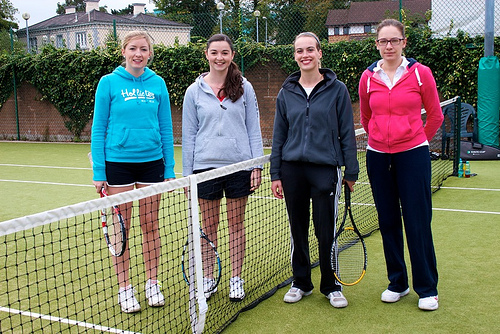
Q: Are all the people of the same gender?
A: Yes, all the people are female.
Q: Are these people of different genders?
A: No, all the people are female.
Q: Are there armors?
A: No, there are no armors.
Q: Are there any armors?
A: No, there are no armors.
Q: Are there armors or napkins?
A: No, there are no armors or napkins.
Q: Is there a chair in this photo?
A: Yes, there is a chair.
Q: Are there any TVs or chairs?
A: Yes, there is a chair.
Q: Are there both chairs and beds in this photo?
A: No, there is a chair but no beds.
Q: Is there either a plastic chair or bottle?
A: Yes, there is a plastic chair.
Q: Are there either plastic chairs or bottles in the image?
A: Yes, there is a plastic chair.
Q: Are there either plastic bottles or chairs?
A: Yes, there is a plastic chair.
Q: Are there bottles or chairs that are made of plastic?
A: Yes, the chair is made of plastic.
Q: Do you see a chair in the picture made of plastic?
A: Yes, there is a chair that is made of plastic.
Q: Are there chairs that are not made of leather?
A: Yes, there is a chair that is made of plastic.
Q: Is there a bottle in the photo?
A: No, there are no bottles.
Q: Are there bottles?
A: No, there are no bottles.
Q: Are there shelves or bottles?
A: No, there are no bottles or shelves.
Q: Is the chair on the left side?
A: No, the chair is on the right of the image.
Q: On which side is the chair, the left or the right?
A: The chair is on the right of the image.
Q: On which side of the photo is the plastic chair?
A: The chair is on the right of the image.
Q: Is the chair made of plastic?
A: Yes, the chair is made of plastic.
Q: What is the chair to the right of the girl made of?
A: The chair is made of plastic.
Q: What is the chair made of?
A: The chair is made of plastic.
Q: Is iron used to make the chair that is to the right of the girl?
A: No, the chair is made of plastic.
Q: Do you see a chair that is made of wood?
A: No, there is a chair but it is made of plastic.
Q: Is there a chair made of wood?
A: No, there is a chair but it is made of plastic.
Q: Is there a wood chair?
A: No, there is a chair but it is made of plastic.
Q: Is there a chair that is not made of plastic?
A: No, there is a chair but it is made of plastic.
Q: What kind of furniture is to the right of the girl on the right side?
A: The piece of furniture is a chair.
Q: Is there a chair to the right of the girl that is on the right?
A: Yes, there is a chair to the right of the girl.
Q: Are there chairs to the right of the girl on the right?
A: Yes, there is a chair to the right of the girl.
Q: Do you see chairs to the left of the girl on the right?
A: No, the chair is to the right of the girl.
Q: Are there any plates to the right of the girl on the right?
A: No, there is a chair to the right of the girl.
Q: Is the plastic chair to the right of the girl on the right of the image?
A: Yes, the chair is to the right of the girl.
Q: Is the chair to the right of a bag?
A: No, the chair is to the right of the girl.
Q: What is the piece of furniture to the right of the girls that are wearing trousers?
A: The piece of furniture is a chair.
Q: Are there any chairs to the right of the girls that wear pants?
A: Yes, there is a chair to the right of the girls.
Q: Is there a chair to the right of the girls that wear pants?
A: Yes, there is a chair to the right of the girls.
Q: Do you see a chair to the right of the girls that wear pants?
A: Yes, there is a chair to the right of the girls.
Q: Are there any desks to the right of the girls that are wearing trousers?
A: No, there is a chair to the right of the girls.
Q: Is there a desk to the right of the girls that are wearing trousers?
A: No, there is a chair to the right of the girls.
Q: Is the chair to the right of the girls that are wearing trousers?
A: Yes, the chair is to the right of the girls.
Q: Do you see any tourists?
A: No, there are no tourists.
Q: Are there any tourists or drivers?
A: No, there are no tourists or drivers.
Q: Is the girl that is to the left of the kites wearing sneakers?
A: Yes, the girl is wearing sneakers.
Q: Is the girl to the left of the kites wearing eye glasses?
A: No, the girl is wearing sneakers.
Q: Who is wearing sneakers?
A: The girl is wearing sneakers.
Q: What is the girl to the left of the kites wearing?
A: The girl is wearing sneakers.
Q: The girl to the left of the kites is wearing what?
A: The girl is wearing sneakers.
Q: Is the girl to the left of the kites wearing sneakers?
A: Yes, the girl is wearing sneakers.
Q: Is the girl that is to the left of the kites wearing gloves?
A: No, the girl is wearing sneakers.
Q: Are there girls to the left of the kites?
A: Yes, there is a girl to the left of the kites.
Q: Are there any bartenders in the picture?
A: No, there are no bartenders.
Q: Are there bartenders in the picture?
A: No, there are no bartenders.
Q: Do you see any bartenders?
A: No, there are no bartenders.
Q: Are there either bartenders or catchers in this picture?
A: No, there are no bartenders or catchers.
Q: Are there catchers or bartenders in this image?
A: No, there are no bartenders or catchers.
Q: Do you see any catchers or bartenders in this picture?
A: No, there are no bartenders or catchers.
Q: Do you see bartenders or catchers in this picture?
A: No, there are no bartenders or catchers.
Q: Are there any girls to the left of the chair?
A: Yes, there is a girl to the left of the chair.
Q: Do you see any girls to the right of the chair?
A: No, the girl is to the left of the chair.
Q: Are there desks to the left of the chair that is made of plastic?
A: No, there is a girl to the left of the chair.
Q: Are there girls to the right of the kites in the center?
A: Yes, there is a girl to the right of the kites.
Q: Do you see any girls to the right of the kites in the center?
A: Yes, there is a girl to the right of the kites.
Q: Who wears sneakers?
A: The girl wears sneakers.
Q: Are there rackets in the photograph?
A: Yes, there is a racket.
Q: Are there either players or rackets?
A: Yes, there is a racket.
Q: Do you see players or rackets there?
A: Yes, there is a racket.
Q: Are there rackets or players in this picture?
A: Yes, there is a racket.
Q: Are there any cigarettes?
A: No, there are no cigarettes.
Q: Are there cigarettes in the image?
A: No, there are no cigarettes.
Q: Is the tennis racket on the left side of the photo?
A: Yes, the tennis racket is on the left of the image.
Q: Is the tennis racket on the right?
A: No, the tennis racket is on the left of the image.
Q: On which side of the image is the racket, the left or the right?
A: The racket is on the left of the image.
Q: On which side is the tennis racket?
A: The tennis racket is on the left of the image.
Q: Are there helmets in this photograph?
A: No, there are no helmets.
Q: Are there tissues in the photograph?
A: No, there are no tissues.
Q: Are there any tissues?
A: No, there are no tissues.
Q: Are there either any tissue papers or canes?
A: No, there are no tissue papers or canes.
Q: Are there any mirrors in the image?
A: No, there are no mirrors.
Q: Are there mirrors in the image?
A: No, there are no mirrors.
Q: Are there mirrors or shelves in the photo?
A: No, there are no mirrors or shelves.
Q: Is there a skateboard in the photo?
A: No, there are no skateboards.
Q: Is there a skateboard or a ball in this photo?
A: No, there are no skateboards or balls.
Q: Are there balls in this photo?
A: No, there are no balls.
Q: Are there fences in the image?
A: Yes, there is a fence.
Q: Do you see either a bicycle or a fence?
A: Yes, there is a fence.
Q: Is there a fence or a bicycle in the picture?
A: Yes, there is a fence.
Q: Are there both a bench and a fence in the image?
A: No, there is a fence but no benches.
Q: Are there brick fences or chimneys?
A: Yes, there is a brick fence.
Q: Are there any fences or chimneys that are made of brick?
A: Yes, the fence is made of brick.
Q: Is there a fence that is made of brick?
A: Yes, there is a fence that is made of brick.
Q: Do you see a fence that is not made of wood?
A: Yes, there is a fence that is made of brick.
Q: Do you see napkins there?
A: No, there are no napkins.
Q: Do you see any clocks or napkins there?
A: No, there are no napkins or clocks.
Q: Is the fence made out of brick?
A: Yes, the fence is made of brick.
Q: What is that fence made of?
A: The fence is made of brick.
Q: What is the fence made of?
A: The fence is made of brick.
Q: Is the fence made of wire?
A: No, the fence is made of brick.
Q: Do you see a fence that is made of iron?
A: No, there is a fence but it is made of brick.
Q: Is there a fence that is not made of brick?
A: No, there is a fence but it is made of brick.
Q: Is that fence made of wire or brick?
A: The fence is made of brick.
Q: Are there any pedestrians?
A: No, there are no pedestrians.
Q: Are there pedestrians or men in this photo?
A: No, there are no pedestrians or men.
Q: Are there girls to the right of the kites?
A: Yes, there are girls to the right of the kites.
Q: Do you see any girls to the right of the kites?
A: Yes, there are girls to the right of the kites.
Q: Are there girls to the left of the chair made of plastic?
A: Yes, there are girls to the left of the chair.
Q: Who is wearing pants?
A: The girls are wearing pants.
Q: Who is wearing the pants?
A: The girls are wearing pants.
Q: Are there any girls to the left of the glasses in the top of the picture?
A: Yes, there are girls to the left of the glasses.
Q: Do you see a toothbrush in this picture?
A: No, there are no toothbrushes.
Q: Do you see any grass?
A: Yes, there is grass.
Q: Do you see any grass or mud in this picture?
A: Yes, there is grass.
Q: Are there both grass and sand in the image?
A: No, there is grass but no sand.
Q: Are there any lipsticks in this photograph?
A: No, there are no lipsticks.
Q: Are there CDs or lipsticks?
A: No, there are no lipsticks or cds.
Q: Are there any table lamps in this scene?
A: No, there are no table lamps.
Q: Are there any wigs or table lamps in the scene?
A: No, there are no table lamps or wigs.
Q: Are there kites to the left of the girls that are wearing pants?
A: Yes, there are kites to the left of the girls.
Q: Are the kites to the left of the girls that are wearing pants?
A: Yes, the kites are to the left of the girls.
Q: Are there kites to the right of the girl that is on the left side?
A: Yes, there are kites to the right of the girl.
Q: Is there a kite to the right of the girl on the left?
A: Yes, there are kites to the right of the girl.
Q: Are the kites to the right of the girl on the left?
A: Yes, the kites are to the right of the girl.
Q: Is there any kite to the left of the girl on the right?
A: Yes, there are kites to the left of the girl.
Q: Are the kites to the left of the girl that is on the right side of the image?
A: Yes, the kites are to the left of the girl.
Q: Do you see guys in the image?
A: No, there are no guys.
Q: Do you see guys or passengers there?
A: No, there are no guys or passengers.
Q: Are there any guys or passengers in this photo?
A: No, there are no guys or passengers.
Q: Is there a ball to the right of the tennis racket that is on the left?
A: No, there is a girl to the right of the racket.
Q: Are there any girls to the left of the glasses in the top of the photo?
A: Yes, there is a girl to the left of the glasses.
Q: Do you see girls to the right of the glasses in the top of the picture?
A: No, the girl is to the left of the glasses.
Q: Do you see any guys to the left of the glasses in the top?
A: No, there is a girl to the left of the glasses.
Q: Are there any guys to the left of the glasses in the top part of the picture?
A: No, there is a girl to the left of the glasses.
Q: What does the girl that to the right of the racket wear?
A: The girl wears sneakers.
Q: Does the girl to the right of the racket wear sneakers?
A: Yes, the girl wears sneakers.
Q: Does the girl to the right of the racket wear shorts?
A: No, the girl wears sneakers.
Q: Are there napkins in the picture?
A: No, there are no napkins.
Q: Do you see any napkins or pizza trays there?
A: No, there are no napkins or pizza trays.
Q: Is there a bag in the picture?
A: No, there are no bags.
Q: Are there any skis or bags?
A: No, there are no bags or skis.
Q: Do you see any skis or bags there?
A: No, there are no bags or skis.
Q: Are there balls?
A: No, there are no balls.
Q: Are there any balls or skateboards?
A: No, there are no balls or skateboards.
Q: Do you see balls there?
A: No, there are no balls.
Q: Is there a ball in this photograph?
A: No, there are no balls.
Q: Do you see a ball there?
A: No, there are no balls.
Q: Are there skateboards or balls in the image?
A: No, there are no balls or skateboards.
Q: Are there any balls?
A: No, there are no balls.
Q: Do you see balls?
A: No, there are no balls.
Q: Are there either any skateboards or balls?
A: No, there are no balls or skateboards.